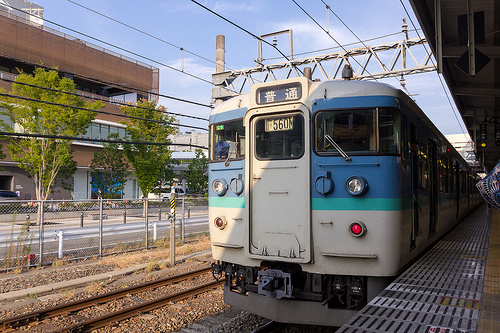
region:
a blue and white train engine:
[194, 73, 456, 330]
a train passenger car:
[450, 150, 478, 219]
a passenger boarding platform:
[359, 202, 496, 332]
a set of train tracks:
[2, 246, 214, 330]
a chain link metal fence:
[3, 192, 148, 272]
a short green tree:
[5, 66, 92, 266]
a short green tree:
[114, 99, 169, 227]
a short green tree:
[85, 133, 125, 207]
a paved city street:
[4, 204, 210, 266]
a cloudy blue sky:
[44, 0, 459, 144]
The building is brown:
[5, 16, 155, 87]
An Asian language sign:
[255, 80, 305, 100]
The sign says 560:
[260, 105, 295, 135]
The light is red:
[345, 218, 363, 239]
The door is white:
[245, 103, 315, 260]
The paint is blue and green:
[315, 157, 402, 214]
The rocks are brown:
[108, 280, 199, 330]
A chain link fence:
[5, 197, 98, 262]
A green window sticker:
[212, 120, 227, 133]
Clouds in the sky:
[160, 52, 216, 93]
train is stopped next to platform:
[204, 76, 485, 328]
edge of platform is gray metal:
[310, 196, 490, 331]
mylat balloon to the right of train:
[475, 160, 498, 210]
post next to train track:
[168, 186, 180, 266]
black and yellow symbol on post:
[169, 191, 176, 209]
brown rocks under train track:
[9, 266, 269, 330]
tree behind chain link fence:
[6, 65, 84, 265]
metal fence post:
[97, 197, 104, 255]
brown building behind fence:
[0, 26, 159, 207]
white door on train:
[247, 102, 307, 261]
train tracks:
[91, 290, 143, 320]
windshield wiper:
[319, 132, 357, 164]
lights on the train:
[336, 176, 376, 202]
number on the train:
[262, 110, 295, 135]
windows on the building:
[94, 118, 119, 145]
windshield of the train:
[209, 120, 244, 163]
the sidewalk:
[487, 233, 498, 273]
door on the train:
[258, 165, 314, 245]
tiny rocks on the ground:
[96, 281, 136, 294]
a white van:
[143, 182, 185, 205]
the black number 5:
[269, 113, 282, 135]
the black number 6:
[276, 115, 290, 138]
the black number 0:
[281, 114, 293, 133]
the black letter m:
[286, 111, 295, 130]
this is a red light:
[328, 214, 382, 241]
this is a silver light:
[341, 172, 378, 200]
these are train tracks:
[26, 222, 213, 332]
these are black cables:
[12, 34, 194, 139]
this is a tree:
[8, 50, 105, 267]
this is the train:
[184, 68, 488, 310]